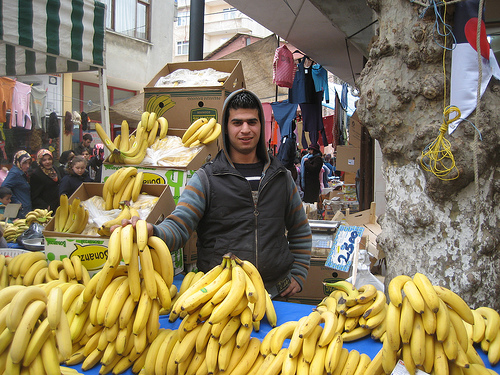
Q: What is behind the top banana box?
A: A pole.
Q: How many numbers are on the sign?
A: Four.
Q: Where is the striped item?
A: Next to the window.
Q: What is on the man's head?
A: A hood.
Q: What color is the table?
A: Blue.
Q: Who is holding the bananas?
A: A man.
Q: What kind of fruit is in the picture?
A: Bananas.